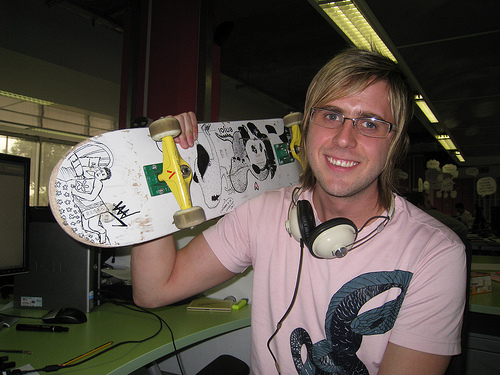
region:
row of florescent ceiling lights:
[315, 0, 469, 164]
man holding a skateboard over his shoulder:
[45, 33, 470, 373]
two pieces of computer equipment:
[0, 151, 105, 316]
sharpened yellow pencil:
[58, 337, 116, 369]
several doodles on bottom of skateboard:
[52, 120, 279, 247]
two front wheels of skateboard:
[142, 114, 209, 232]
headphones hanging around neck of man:
[264, 181, 397, 373]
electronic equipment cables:
[2, 299, 187, 373]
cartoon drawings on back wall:
[412, 157, 497, 205]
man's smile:
[321, 153, 366, 173]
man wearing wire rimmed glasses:
[297, 46, 403, 201]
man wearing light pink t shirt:
[201, 47, 477, 374]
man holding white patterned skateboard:
[37, 22, 477, 373]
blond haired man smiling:
[294, 43, 413, 210]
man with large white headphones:
[271, 43, 408, 268]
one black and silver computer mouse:
[31, 303, 91, 328]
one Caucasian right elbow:
[126, 265, 191, 310]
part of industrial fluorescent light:
[322, 0, 385, 48]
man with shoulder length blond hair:
[291, 45, 410, 218]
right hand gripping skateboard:
[48, 106, 215, 241]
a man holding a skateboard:
[28, 48, 468, 373]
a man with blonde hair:
[303, 50, 418, 218]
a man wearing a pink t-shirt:
[228, 45, 459, 369]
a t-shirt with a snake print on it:
[194, 188, 466, 374]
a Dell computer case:
[12, 217, 104, 316]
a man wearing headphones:
[261, 46, 412, 261]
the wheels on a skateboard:
[141, 116, 213, 235]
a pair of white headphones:
[278, 196, 372, 266]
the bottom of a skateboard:
[36, 126, 311, 243]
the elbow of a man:
[124, 288, 147, 312]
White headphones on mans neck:
[260, 143, 440, 273]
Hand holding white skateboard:
[105, 90, 242, 208]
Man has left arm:
[378, 180, 477, 370]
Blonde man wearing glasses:
[292, 43, 437, 198]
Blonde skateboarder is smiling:
[279, 58, 419, 205]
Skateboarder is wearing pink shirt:
[176, 148, 474, 370]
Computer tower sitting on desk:
[8, 97, 130, 340]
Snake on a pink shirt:
[276, 255, 426, 372]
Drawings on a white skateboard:
[30, 133, 166, 257]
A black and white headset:
[283, 192, 363, 264]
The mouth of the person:
[321, 150, 362, 175]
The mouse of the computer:
[35, 300, 91, 327]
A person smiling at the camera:
[120, 30, 465, 370]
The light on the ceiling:
[430, 130, 455, 150]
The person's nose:
[330, 111, 356, 147]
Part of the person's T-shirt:
[257, 247, 291, 294]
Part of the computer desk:
[95, 313, 129, 337]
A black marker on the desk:
[11, 318, 72, 335]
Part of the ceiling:
[245, 23, 302, 83]